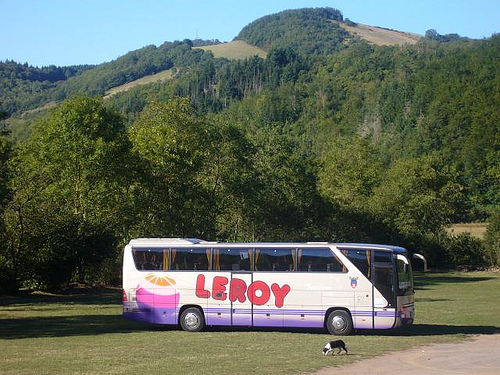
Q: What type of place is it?
A: It is a field.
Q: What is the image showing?
A: It is showing a field.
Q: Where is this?
A: This is at the field.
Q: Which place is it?
A: It is a field.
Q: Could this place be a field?
A: Yes, it is a field.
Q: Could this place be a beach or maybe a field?
A: It is a field.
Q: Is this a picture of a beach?
A: No, the picture is showing a field.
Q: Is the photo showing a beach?
A: No, the picture is showing a field.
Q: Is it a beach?
A: No, it is a field.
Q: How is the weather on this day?
A: It is clear.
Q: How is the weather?
A: It is clear.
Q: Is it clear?
A: Yes, it is clear.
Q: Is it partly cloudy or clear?
A: It is clear.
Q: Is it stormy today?
A: No, it is clear.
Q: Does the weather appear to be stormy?
A: No, it is clear.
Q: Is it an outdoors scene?
A: Yes, it is outdoors.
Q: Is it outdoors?
A: Yes, it is outdoors.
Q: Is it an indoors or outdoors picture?
A: It is outdoors.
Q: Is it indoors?
A: No, it is outdoors.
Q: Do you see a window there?
A: Yes, there are windows.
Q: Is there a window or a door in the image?
A: Yes, there are windows.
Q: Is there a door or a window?
A: Yes, there are windows.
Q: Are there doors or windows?
A: Yes, there are windows.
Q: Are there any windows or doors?
A: Yes, there are windows.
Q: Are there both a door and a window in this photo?
A: Yes, there are both a window and a door.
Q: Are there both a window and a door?
A: Yes, there are both a window and a door.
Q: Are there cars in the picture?
A: No, there are no cars.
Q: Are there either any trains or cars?
A: No, there are no cars or trains.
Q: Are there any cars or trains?
A: No, there are no cars or trains.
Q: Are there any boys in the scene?
A: No, there are no boys.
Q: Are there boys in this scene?
A: No, there are no boys.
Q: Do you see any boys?
A: No, there are no boys.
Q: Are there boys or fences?
A: No, there are no boys or fences.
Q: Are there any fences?
A: No, there are no fences.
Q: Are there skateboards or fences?
A: No, there are no fences or skateboards.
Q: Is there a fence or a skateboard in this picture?
A: No, there are no fences or skateboards.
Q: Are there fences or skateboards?
A: No, there are no fences or skateboards.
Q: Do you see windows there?
A: Yes, there are windows.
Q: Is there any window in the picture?
A: Yes, there are windows.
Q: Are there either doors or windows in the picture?
A: Yes, there are windows.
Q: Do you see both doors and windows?
A: Yes, there are both windows and a door.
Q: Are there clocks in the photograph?
A: No, there are no clocks.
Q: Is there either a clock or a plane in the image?
A: No, there are no clocks or airplanes.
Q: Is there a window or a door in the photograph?
A: Yes, there are windows.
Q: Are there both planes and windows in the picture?
A: No, there are windows but no airplanes.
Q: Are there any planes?
A: No, there are no planes.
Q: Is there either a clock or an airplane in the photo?
A: No, there are no airplanes or clocks.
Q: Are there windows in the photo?
A: Yes, there are windows.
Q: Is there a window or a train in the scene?
A: Yes, there are windows.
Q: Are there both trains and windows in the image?
A: No, there are windows but no trains.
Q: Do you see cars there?
A: No, there are no cars.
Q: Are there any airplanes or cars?
A: No, there are no cars or airplanes.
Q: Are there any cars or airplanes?
A: No, there are no cars or airplanes.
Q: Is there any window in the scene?
A: Yes, there are windows.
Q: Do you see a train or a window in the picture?
A: Yes, there are windows.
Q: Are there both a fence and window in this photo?
A: No, there are windows but no fences.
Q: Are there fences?
A: No, there are no fences.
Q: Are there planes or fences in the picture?
A: No, there are no fences or planes.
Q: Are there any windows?
A: Yes, there are windows.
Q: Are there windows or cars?
A: Yes, there are windows.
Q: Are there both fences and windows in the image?
A: No, there are windows but no fences.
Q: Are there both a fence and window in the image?
A: No, there are windows but no fences.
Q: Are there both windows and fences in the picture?
A: No, there are windows but no fences.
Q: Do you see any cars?
A: No, there are no cars.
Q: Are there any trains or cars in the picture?
A: No, there are no cars or trains.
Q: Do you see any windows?
A: Yes, there are windows.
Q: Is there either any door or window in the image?
A: Yes, there are windows.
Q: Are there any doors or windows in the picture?
A: Yes, there are windows.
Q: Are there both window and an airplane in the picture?
A: No, there are windows but no airplanes.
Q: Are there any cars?
A: No, there are no cars.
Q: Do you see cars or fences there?
A: No, there are no cars or fences.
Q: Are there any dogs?
A: Yes, there is a dog.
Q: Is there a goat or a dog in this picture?
A: Yes, there is a dog.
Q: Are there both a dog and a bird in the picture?
A: No, there is a dog but no birds.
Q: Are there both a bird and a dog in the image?
A: No, there is a dog but no birds.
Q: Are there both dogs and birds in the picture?
A: No, there is a dog but no birds.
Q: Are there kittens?
A: No, there are no kittens.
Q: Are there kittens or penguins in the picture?
A: No, there are no kittens or penguins.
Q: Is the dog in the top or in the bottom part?
A: The dog is in the bottom of the image.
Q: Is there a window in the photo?
A: Yes, there are windows.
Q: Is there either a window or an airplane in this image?
A: Yes, there are windows.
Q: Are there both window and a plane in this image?
A: No, there are windows but no airplanes.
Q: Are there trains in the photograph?
A: No, there are no trains.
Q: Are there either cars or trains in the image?
A: No, there are no trains or cars.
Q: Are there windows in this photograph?
A: Yes, there are windows.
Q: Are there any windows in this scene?
A: Yes, there are windows.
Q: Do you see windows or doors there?
A: Yes, there are windows.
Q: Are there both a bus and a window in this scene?
A: Yes, there are both a window and a bus.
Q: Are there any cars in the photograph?
A: No, there are no cars.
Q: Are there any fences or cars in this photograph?
A: No, there are no cars or fences.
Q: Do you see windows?
A: Yes, there is a window.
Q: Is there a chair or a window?
A: Yes, there is a window.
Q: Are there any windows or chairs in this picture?
A: Yes, there is a window.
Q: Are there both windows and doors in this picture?
A: Yes, there are both a window and a door.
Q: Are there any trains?
A: No, there are no trains.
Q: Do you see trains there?
A: No, there are no trains.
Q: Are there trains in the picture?
A: No, there are no trains.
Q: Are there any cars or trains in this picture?
A: No, there are no trains or cars.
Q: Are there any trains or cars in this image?
A: No, there are no trains or cars.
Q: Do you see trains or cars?
A: No, there are no trains or cars.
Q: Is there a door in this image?
A: Yes, there is a door.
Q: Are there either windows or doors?
A: Yes, there is a door.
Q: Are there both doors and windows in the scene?
A: Yes, there are both a door and a window.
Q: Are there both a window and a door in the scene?
A: Yes, there are both a door and a window.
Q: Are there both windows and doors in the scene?
A: Yes, there are both a door and a window.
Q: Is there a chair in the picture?
A: No, there are no chairs.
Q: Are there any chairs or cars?
A: No, there are no chairs or cars.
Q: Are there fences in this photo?
A: No, there are no fences.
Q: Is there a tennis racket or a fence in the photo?
A: No, there are no fences or rackets.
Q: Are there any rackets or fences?
A: No, there are no fences or rackets.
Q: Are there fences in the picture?
A: No, there are no fences.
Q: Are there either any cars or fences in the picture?
A: No, there are no fences or cars.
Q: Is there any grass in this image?
A: Yes, there is grass.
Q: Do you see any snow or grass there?
A: Yes, there is grass.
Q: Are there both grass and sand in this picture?
A: No, there is grass but no sand.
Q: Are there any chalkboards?
A: No, there are no chalkboards.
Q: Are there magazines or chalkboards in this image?
A: No, there are no chalkboards or magazines.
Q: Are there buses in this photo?
A: Yes, there is a bus.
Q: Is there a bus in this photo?
A: Yes, there is a bus.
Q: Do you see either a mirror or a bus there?
A: Yes, there is a bus.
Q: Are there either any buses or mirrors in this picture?
A: Yes, there is a bus.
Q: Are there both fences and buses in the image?
A: No, there is a bus but no fences.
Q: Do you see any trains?
A: No, there are no trains.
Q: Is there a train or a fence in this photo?
A: No, there are no trains or fences.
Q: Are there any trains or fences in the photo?
A: No, there are no trains or fences.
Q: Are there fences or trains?
A: No, there are no trains or fences.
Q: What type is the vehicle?
A: The vehicle is a bus.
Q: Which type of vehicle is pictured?
A: The vehicle is a bus.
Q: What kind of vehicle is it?
A: The vehicle is a bus.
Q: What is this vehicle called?
A: That is a bus.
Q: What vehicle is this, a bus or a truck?
A: That is a bus.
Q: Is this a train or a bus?
A: This is a bus.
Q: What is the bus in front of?
A: The bus is in front of the trees.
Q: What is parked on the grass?
A: The bus is parked on the grass.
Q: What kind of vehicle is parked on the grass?
A: The vehicle is a bus.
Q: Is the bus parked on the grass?
A: Yes, the bus is parked on the grass.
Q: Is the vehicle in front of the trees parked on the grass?
A: Yes, the bus is parked on the grass.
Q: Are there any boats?
A: No, there are no boats.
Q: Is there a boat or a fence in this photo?
A: No, there are no boats or fences.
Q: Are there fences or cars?
A: No, there are no cars or fences.